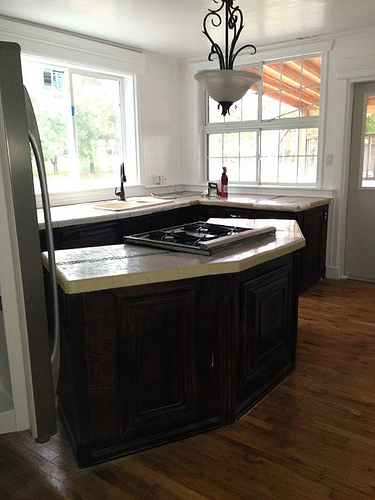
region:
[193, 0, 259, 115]
a light hanging from the ceiling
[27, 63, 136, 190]
a window behind the sink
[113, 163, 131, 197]
the faucet on the sink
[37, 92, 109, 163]
trees outside the window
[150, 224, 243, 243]
the range on the counter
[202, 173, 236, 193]
items on the counter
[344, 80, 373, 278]
a door in the kitchen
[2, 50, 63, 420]
a refrigerator in the kitchen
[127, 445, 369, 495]
hardwood floor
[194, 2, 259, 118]
Drop light fixture with school house glass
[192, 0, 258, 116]
Drop light fixture with black metal and white glass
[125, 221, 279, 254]
Four burner gas stove top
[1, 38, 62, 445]
Opened door of brushed stainless steel refrigerator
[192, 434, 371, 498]
Brown stained wooden flooring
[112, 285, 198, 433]
Raised panel false cabinet door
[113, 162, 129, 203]
Single handle black high access kitchen faucet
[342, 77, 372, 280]
Grey painted, single window door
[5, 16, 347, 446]
this is a kitchen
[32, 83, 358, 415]
the kitchen is neat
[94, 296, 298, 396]
these are cabinets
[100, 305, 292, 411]
the cabinets are wooden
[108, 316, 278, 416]
the cabinets are dark brown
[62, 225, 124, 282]
the counter is tiled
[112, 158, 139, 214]
the facet is black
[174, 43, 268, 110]
this is a hanging light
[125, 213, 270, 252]
the stovetop on the counter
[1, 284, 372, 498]
the wooden floor in the kitchen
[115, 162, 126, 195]
the faucet by the sink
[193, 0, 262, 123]
the light hanging from the building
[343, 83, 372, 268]
the door leading outside to the yard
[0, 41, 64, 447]
the door for the fridge just hanging around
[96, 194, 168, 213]
the sink sitting in the kitchen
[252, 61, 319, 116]
the cover for the patio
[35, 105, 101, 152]
the green leafy trees outside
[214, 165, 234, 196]
a bottle sitting on the counter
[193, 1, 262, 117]
Light fixture hanging from ceiling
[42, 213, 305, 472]
Dark wooden island in middle of kitchen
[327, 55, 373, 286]
Cream colored door in kitchen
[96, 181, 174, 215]
Sink built into countertop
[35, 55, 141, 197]
Paned glass window above sink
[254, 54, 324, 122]
Red, yellow and orange awning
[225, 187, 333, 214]
Cream colored counter top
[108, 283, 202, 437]
Dark wooden cabinet door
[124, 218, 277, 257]
Stove top on counter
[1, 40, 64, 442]
Silver refrigerator door next to island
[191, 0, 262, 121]
Lamp hanging on the ceiling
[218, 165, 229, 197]
Bottle sitting on the counter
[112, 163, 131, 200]
Black faucet in front of the window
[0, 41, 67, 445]
Refrigerator door is opened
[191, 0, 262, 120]
Lamp above the counter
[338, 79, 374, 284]
Door next to a window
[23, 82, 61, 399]
Gray handle on the refrigerator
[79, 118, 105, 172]
green leaves on the tree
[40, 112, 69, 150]
green leaves on the tree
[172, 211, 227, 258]
a black burner on the stove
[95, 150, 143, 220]
a sink in the kitchen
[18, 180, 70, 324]
a silver fridge handle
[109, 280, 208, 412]
a brown cabinet door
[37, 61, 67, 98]
Stickers on a window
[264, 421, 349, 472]
Hard wood floor